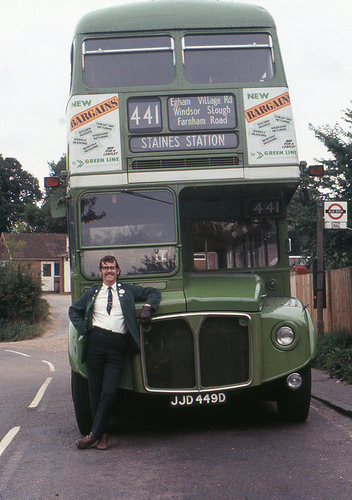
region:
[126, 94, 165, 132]
Bus number on front of the bus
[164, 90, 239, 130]
Sign on front of bus to display route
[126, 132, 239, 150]
Sign on the front of the bus to display station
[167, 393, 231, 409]
License plate on front of passenger bus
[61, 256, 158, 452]
Bus driver posing for a photograph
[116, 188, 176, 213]
Windshield wiper on the windshield of bus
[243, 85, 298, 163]
Advertising on the front of the bus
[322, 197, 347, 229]
Street sign next to road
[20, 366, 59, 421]
White lines painted on the street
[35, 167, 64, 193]
Turn signal of passenger bus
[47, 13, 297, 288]
green double decker bus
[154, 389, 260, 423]
black and white license plate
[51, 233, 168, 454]
man leaning on bus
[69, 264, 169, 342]
white shirt and green coat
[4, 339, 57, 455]
white lines painted on road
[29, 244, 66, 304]
white door on brick building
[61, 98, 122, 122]
yellow and black sign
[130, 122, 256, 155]
black sign with white writing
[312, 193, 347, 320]
red, white, and black sign on pole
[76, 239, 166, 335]
man wearing dark glove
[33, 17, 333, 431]
double decker bus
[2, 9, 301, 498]
large green bus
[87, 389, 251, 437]
license plate on a bus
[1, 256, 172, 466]
man with mustache on bus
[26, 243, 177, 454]
man in a suit leaning on bus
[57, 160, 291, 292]
front windshield of bus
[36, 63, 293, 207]
images on side of a bus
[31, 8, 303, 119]
top front windshields on bus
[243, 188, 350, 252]
street sign by bus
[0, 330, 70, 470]
white lines on the road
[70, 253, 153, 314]
The man has several buttons on his jacket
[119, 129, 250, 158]
The bus is set to go to Staines Station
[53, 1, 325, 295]
The bus is a double decker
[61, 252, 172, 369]
The man is happy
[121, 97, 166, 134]
The bus number is 441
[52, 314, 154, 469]
The man has his feet crossed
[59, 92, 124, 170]
The company is offering Bargain prices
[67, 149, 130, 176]
The Bus is apart of the Green Line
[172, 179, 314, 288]
One side of the bus has no front window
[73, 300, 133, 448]
The man has on tight pants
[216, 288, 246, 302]
edge of a bonnet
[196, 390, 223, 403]
part of a plate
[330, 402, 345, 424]
edge of a road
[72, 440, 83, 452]
edge of a shoe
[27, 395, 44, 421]
edge of a line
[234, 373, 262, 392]
edge of a bus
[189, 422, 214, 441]
edge of a shade